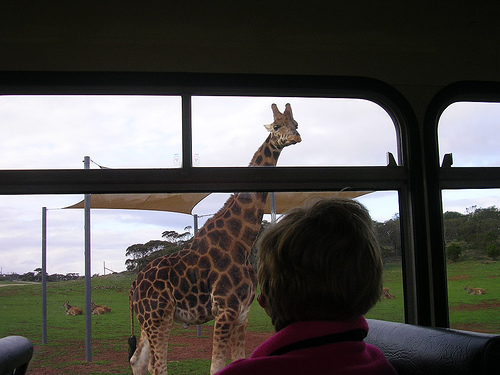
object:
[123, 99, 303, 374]
giraffe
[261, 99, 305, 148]
head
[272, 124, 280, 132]
eye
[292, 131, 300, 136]
nose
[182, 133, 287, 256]
neck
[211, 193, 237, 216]
mane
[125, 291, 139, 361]
tail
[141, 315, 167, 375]
legs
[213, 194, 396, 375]
person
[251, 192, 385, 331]
head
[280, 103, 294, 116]
ears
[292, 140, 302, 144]
mouth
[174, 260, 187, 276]
spots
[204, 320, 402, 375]
jacket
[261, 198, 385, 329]
hair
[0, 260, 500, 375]
grass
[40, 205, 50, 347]
pole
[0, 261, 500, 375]
ground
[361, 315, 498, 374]
seat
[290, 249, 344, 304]
back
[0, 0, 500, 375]
bus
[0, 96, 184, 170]
window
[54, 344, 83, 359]
patch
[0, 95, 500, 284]
sky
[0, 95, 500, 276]
clouds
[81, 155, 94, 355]
post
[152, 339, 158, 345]
stripes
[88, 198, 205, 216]
caopies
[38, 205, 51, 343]
poles